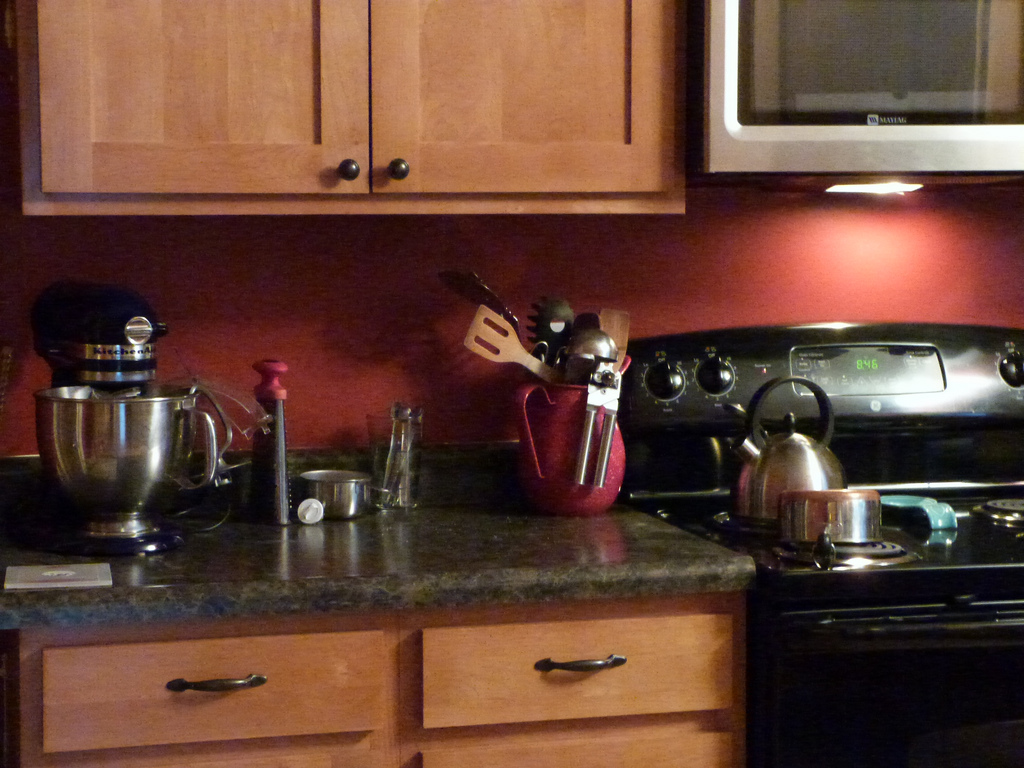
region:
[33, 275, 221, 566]
standing mixer on the counter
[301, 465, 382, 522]
metal measuring cup on the counter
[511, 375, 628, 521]
jug full of cooking utensils on the counter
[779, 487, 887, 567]
small pan on the stovetop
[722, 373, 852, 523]
tea kettle on the stovetop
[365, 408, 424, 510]
glass with spoons on the counter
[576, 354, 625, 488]
can opener in the jug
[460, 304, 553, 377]
wooden spatula in the jug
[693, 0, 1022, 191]
microwave oven above the stovetop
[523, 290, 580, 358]
spaghetti server in the jug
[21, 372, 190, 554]
a bowl is color silver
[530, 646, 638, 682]
a handle is black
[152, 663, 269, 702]
a handle is black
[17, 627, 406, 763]
a drawer under a counter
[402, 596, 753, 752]
a drawer under a counter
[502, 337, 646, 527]
a jar is color pink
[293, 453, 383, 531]
a bowl is silver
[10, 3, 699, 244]
the cabin is color brown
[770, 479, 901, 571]
the pot on the burner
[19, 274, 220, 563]
stand mixer on the counter top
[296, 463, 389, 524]
measuring cup on the counter top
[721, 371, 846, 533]
silver tea kettle on the stove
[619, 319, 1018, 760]
black electric stove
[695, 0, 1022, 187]
stainless steel microwave above a stove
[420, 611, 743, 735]
wooden brown drawer in a kitchen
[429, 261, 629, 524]
red container holding several utensils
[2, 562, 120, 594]
dvd case on the counter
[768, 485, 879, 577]
saucepan sitting upside down on the stove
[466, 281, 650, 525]
Red jug holding kitchen utensils.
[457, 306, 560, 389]
Spatula for cooking food.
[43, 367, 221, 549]
Silver bowl below the mixer.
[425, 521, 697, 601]
Dark granite counter top in the kitchen.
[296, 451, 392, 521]
Silver bowl on the counter.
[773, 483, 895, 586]
Silver saucepan on the stove.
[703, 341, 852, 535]
Silver teakettle on the stove.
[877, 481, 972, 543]
Blue dish to rest a spoon.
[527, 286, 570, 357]
A utensil meant for cooking.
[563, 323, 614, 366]
A utensil meant for cooking.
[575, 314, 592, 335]
A utensil meant for cooking.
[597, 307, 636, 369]
A utensil meant for cooking.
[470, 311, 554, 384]
A utensil meant for cooking.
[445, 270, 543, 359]
A utensil meant for cooking.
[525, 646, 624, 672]
A handle on wood.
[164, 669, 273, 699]
A handle on wood.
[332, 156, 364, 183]
A handle on wood.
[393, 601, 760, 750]
wood drawer with handle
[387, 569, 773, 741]
wood drawer with handle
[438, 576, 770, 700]
wood drawer with handle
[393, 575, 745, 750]
wood drawer with handle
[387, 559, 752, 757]
wood drawer with handle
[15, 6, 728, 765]
Brown wooden cabinets.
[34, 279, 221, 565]
A dark blue and silver kitchen mixer.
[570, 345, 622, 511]
A silver manual can opener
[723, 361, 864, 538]
A silver teakettle with a black handle.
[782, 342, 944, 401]
A display on a stove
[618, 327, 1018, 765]
A black stove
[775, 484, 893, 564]
A silver pot with a black handle.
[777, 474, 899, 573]
A pot turned upside down on a stovetop burner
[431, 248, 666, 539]
Cooking utensils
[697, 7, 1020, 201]
A stainless steel microwave over the stove